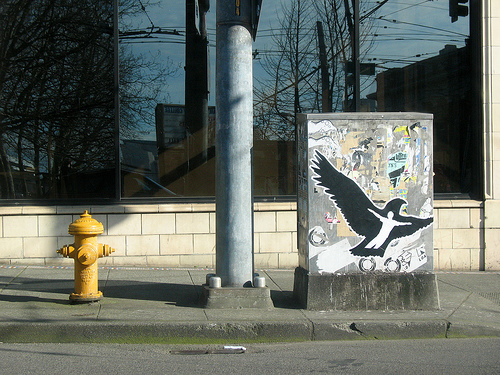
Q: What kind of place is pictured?
A: It is a sidewalk.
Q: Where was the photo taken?
A: It was taken at the sidewalk.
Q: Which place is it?
A: It is a sidewalk.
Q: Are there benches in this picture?
A: No, there are no benches.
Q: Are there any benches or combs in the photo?
A: No, there are no benches or combs.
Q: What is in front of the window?
A: The pole is in front of the window.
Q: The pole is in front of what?
A: The pole is in front of the window.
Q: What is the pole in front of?
A: The pole is in front of the window.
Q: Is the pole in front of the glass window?
A: Yes, the pole is in front of the window.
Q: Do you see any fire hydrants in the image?
A: Yes, there is a fire hydrant.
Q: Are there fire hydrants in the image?
A: Yes, there is a fire hydrant.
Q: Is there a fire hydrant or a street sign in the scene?
A: Yes, there is a fire hydrant.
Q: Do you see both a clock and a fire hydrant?
A: No, there is a fire hydrant but no clocks.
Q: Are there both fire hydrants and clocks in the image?
A: No, there is a fire hydrant but no clocks.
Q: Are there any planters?
A: No, there are no planters.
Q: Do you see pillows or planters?
A: No, there are no planters or pillows.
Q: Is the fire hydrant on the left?
A: Yes, the fire hydrant is on the left of the image.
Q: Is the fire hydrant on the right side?
A: No, the fire hydrant is on the left of the image.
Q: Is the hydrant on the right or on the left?
A: The hydrant is on the left of the image.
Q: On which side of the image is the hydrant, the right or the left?
A: The hydrant is on the left of the image.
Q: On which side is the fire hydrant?
A: The fire hydrant is on the left of the image.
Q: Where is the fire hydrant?
A: The fire hydrant is on the sidewalk.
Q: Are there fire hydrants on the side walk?
A: Yes, there is a fire hydrant on the side walk.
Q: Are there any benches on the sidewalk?
A: No, there is a fire hydrant on the sidewalk.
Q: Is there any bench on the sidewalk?
A: No, there is a fire hydrant on the sidewalk.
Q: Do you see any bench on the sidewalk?
A: No, there is a fire hydrant on the sidewalk.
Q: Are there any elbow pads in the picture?
A: No, there are no elbow pads.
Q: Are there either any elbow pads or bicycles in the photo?
A: No, there are no elbow pads or bicycles.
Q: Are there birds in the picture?
A: Yes, there is a bird.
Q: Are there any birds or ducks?
A: Yes, there is a bird.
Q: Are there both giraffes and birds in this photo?
A: No, there is a bird but no giraffes.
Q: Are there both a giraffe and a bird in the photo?
A: No, there is a bird but no giraffes.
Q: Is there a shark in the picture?
A: No, there are no sharks.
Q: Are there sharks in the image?
A: No, there are no sharks.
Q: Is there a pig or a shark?
A: No, there are no sharks or pigs.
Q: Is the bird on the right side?
A: Yes, the bird is on the right of the image.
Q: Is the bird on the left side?
A: No, the bird is on the right of the image.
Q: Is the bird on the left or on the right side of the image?
A: The bird is on the right of the image.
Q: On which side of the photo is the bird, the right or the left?
A: The bird is on the right of the image.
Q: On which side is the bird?
A: The bird is on the right of the image.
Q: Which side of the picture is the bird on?
A: The bird is on the right of the image.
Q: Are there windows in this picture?
A: Yes, there is a window.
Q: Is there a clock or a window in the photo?
A: Yes, there is a window.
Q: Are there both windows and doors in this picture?
A: No, there is a window but no doors.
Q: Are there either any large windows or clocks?
A: Yes, there is a large window.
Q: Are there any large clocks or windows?
A: Yes, there is a large window.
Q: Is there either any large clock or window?
A: Yes, there is a large window.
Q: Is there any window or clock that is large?
A: Yes, the window is large.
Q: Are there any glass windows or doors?
A: Yes, there is a glass window.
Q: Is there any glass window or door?
A: Yes, there is a glass window.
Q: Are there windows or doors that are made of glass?
A: Yes, the window is made of glass.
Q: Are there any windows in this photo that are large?
A: Yes, there is a large window.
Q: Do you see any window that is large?
A: Yes, there is a window that is large.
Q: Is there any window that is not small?
A: Yes, there is a large window.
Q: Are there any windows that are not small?
A: Yes, there is a large window.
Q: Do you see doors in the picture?
A: No, there are no doors.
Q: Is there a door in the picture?
A: No, there are no doors.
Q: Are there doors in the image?
A: No, there are no doors.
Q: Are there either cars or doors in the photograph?
A: No, there are no doors or cars.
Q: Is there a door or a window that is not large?
A: No, there is a window but it is large.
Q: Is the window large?
A: Yes, the window is large.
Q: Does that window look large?
A: Yes, the window is large.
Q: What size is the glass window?
A: The window is large.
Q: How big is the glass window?
A: The window is large.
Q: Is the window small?
A: No, the window is large.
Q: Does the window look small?
A: No, the window is large.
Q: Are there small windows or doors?
A: No, there is a window but it is large.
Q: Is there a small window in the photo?
A: No, there is a window but it is large.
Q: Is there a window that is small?
A: No, there is a window but it is large.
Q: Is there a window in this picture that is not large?
A: No, there is a window but it is large.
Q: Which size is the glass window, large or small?
A: The window is large.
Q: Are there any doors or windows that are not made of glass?
A: No, there is a window but it is made of glass.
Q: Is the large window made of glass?
A: Yes, the window is made of glass.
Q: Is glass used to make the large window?
A: Yes, the window is made of glass.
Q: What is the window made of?
A: The window is made of glass.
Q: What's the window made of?
A: The window is made of glass.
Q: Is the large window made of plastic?
A: No, the window is made of glass.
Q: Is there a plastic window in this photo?
A: No, there is a window but it is made of glass.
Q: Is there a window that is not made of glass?
A: No, there is a window but it is made of glass.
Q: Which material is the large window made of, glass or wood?
A: The window is made of glass.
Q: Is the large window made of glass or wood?
A: The window is made of glass.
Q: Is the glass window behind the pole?
A: Yes, the window is behind the pole.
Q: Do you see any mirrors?
A: No, there are no mirrors.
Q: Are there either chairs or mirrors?
A: No, there are no mirrors or chairs.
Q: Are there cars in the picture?
A: No, there are no cars.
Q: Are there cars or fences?
A: No, there are no cars or fences.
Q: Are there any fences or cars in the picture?
A: No, there are no cars or fences.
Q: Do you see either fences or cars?
A: No, there are no cars or fences.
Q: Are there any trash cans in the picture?
A: No, there are no trash cans.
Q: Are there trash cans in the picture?
A: No, there are no trash cans.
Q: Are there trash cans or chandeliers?
A: No, there are no trash cans or chandeliers.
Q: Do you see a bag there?
A: No, there are no bags.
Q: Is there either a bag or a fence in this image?
A: No, there are no bags or fences.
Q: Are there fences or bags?
A: No, there are no bags or fences.